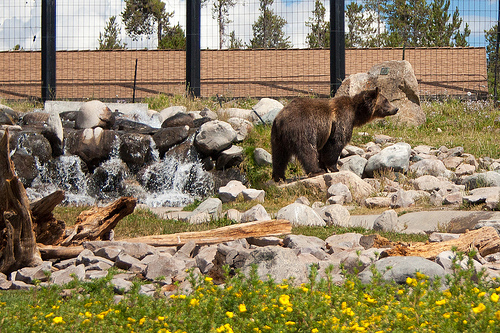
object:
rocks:
[75, 99, 111, 129]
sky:
[4, 3, 494, 48]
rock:
[362, 256, 443, 287]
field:
[2, 70, 484, 332]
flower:
[73, 272, 467, 331]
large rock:
[38, 267, 92, 287]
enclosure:
[6, 119, 477, 294]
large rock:
[193, 118, 243, 148]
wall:
[4, 50, 494, 93]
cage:
[1, 0, 498, 102]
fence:
[2, 2, 492, 97]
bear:
[271, 85, 399, 181]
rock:
[458, 170, 498, 191]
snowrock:
[371, 137, 413, 173]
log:
[359, 214, 497, 273]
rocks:
[16, 260, 51, 282]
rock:
[76, 122, 117, 163]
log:
[29, 200, 268, 266]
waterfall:
[54, 154, 218, 201]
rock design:
[3, 110, 498, 295]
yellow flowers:
[386, 275, 500, 333]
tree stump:
[0, 132, 42, 278]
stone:
[18, 112, 92, 170]